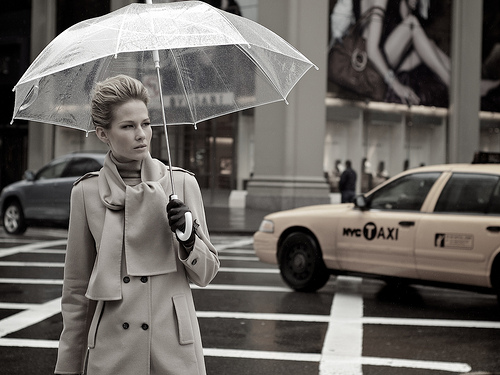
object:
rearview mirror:
[353, 190, 372, 210]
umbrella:
[9, 0, 318, 241]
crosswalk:
[0, 230, 500, 375]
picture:
[323, 0, 456, 107]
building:
[0, 2, 500, 214]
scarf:
[83, 151, 178, 301]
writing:
[164, 91, 234, 110]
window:
[212, 108, 238, 142]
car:
[251, 162, 500, 293]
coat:
[55, 163, 222, 374]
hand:
[164, 197, 198, 234]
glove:
[163, 198, 201, 259]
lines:
[360, 315, 499, 327]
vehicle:
[0, 150, 108, 239]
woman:
[54, 72, 220, 374]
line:
[200, 344, 320, 361]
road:
[1, 230, 500, 375]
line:
[187, 282, 292, 293]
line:
[0, 301, 38, 313]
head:
[90, 73, 154, 160]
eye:
[117, 122, 133, 128]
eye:
[142, 120, 150, 129]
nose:
[134, 124, 148, 142]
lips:
[130, 144, 149, 153]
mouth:
[132, 143, 150, 153]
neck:
[108, 147, 149, 173]